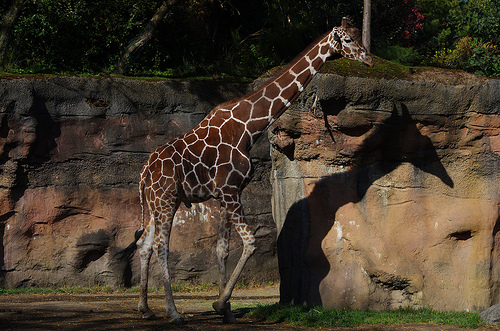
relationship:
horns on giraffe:
[338, 10, 349, 25] [104, 17, 373, 326]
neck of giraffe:
[248, 51, 339, 127] [124, 7, 371, 300]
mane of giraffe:
[246, 29, 335, 105] [104, 17, 373, 326]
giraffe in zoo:
[104, 17, 373, 326] [8, 5, 494, 322]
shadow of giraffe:
[263, 103, 453, 316] [104, 17, 373, 326]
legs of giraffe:
[125, 209, 197, 323] [104, 17, 373, 326]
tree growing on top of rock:
[107, 1, 175, 71] [9, 72, 249, 107]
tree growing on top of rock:
[347, 2, 395, 73] [9, 72, 249, 107]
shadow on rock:
[263, 99, 454, 306] [267, 70, 494, 315]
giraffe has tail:
[104, 17, 373, 326] [133, 158, 150, 241]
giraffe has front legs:
[104, 17, 373, 326] [210, 190, 257, 312]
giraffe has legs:
[117, 12, 378, 329] [132, 212, 194, 329]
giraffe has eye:
[104, 17, 373, 326] [342, 36, 354, 44]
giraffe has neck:
[104, 17, 373, 326] [230, 39, 335, 132]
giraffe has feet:
[117, 12, 378, 329] [130, 280, 246, 322]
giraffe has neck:
[117, 12, 378, 329] [252, 36, 332, 113]